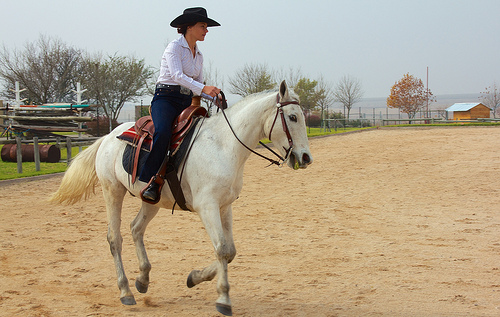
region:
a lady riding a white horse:
[51, 3, 321, 310]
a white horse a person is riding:
[47, 91, 317, 312]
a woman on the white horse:
[133, 3, 225, 212]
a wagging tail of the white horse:
[36, 121, 109, 216]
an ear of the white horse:
[274, 77, 290, 100]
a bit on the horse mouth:
[284, 150, 308, 172]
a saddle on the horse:
[181, 92, 205, 140]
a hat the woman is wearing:
[168, 3, 220, 30]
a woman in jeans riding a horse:
[128, 4, 323, 228]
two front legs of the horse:
[182, 193, 244, 313]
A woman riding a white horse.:
[53, 5, 309, 315]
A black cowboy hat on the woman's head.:
[165, 5, 221, 26]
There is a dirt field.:
[1, 121, 496, 306]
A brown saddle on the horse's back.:
[131, 90, 211, 135]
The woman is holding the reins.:
[205, 83, 223, 106]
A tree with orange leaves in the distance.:
[385, 70, 435, 121]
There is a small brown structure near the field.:
[445, 97, 485, 119]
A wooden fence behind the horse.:
[0, 135, 100, 170]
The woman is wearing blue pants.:
[150, 82, 190, 187]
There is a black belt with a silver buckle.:
[156, 85, 191, 96]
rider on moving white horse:
[46, 3, 313, 309]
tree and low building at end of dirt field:
[375, 65, 495, 125]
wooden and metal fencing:
[322, 100, 452, 125]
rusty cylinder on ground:
[1, 131, 61, 161]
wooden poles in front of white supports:
[2, 80, 87, 135]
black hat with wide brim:
[132, 5, 222, 205]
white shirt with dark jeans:
[106, 30, 202, 232]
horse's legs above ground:
[95, 250, 213, 312]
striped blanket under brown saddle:
[115, 102, 195, 157]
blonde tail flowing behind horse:
[45, 132, 106, 207]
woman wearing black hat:
[164, 2, 225, 41]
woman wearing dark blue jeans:
[136, 84, 203, 199]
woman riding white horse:
[82, 75, 372, 314]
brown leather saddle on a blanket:
[91, 90, 230, 233]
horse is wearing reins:
[230, 79, 340, 208]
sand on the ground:
[211, 153, 453, 308]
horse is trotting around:
[86, 223, 291, 314]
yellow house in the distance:
[424, 92, 493, 157]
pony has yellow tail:
[40, 120, 127, 221]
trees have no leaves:
[25, 41, 356, 153]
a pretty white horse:
[47, 78, 314, 315]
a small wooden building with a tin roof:
[445, 99, 492, 123]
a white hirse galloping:
[50, 77, 317, 315]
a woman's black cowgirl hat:
[168, 8, 223, 28]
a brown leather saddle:
[119, 92, 208, 214]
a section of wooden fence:
[0, 135, 95, 173]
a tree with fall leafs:
[383, 70, 436, 129]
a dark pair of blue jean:
[138, 80, 194, 171]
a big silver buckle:
[178, 83, 192, 96]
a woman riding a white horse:
[49, 8, 317, 313]